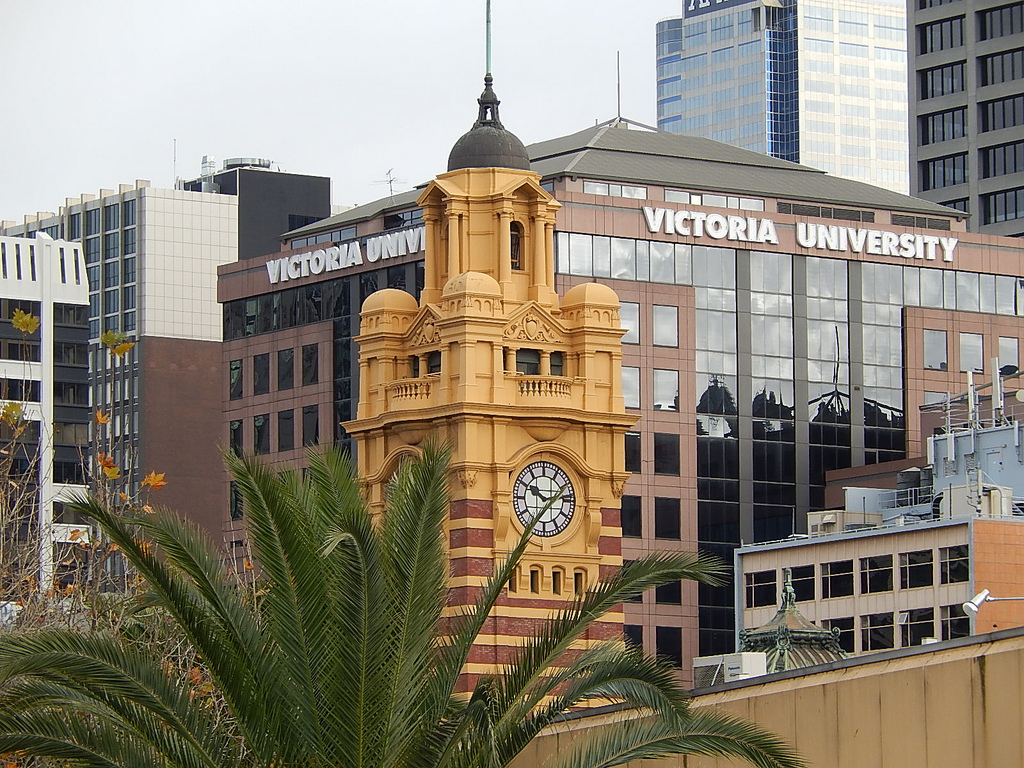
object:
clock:
[508, 454, 578, 543]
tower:
[343, 46, 627, 702]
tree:
[2, 451, 769, 766]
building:
[531, 656, 1023, 765]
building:
[358, 74, 634, 698]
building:
[562, 178, 1017, 567]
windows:
[851, 555, 892, 593]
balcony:
[517, 375, 578, 401]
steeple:
[436, 4, 535, 169]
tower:
[361, 0, 624, 716]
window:
[753, 253, 792, 291]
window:
[753, 383, 795, 420]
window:
[755, 445, 798, 537]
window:
[756, 484, 795, 538]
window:
[694, 415, 738, 479]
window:
[658, 332, 680, 542]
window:
[654, 371, 681, 410]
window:
[655, 305, 679, 353]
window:
[570, 234, 593, 275]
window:
[652, 432, 682, 477]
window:
[593, 236, 611, 280]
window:
[698, 499, 739, 544]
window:
[611, 239, 633, 281]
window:
[755, 418, 796, 482]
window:
[651, 242, 675, 284]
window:
[675, 244, 692, 286]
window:
[693, 249, 736, 288]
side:
[465, 0, 625, 716]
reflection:
[630, 364, 921, 604]